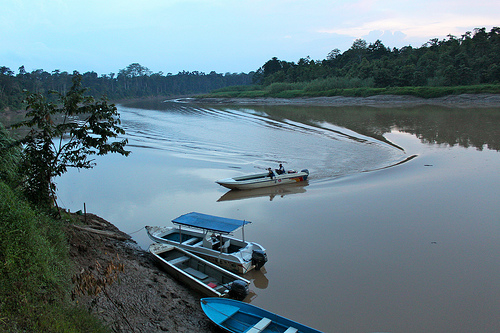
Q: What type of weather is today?
A: It is clear.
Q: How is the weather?
A: It is clear.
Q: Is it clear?
A: Yes, it is clear.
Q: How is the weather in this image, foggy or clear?
A: It is clear.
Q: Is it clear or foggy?
A: It is clear.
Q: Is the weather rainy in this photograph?
A: No, it is clear.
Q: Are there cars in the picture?
A: No, there are no cars.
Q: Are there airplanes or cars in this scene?
A: No, there are no cars or airplanes.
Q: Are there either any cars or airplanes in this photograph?
A: No, there are no cars or airplanes.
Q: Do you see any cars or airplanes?
A: No, there are no cars or airplanes.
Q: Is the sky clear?
A: Yes, the sky is clear.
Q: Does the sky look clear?
A: Yes, the sky is clear.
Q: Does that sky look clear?
A: Yes, the sky is clear.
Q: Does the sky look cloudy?
A: No, the sky is clear.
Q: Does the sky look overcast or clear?
A: The sky is clear.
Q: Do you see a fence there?
A: No, there are no fences.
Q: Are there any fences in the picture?
A: No, there are no fences.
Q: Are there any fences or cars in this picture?
A: No, there are no fences or cars.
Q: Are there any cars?
A: No, there are no cars.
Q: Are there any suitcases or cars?
A: No, there are no cars or suitcases.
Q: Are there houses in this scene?
A: No, there are no houses.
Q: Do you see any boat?
A: Yes, there is a boat.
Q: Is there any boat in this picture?
A: Yes, there is a boat.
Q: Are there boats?
A: Yes, there is a boat.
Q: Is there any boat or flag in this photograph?
A: Yes, there is a boat.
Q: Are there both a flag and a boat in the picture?
A: No, there is a boat but no flags.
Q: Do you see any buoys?
A: No, there are no buoys.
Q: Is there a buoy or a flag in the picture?
A: No, there are no buoys or flags.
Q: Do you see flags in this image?
A: No, there are no flags.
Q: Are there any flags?
A: No, there are no flags.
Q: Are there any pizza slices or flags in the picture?
A: No, there are no flags or pizza slices.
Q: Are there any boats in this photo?
A: Yes, there is a boat.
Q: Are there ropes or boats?
A: Yes, there is a boat.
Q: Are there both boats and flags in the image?
A: No, there is a boat but no flags.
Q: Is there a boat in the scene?
A: Yes, there is a boat.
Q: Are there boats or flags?
A: Yes, there is a boat.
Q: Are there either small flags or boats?
A: Yes, there is a small boat.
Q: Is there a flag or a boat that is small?
A: Yes, the boat is small.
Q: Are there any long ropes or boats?
A: Yes, there is a long boat.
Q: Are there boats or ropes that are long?
A: Yes, the boat is long.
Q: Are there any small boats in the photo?
A: Yes, there is a small boat.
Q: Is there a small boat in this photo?
A: Yes, there is a small boat.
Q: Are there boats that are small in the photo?
A: Yes, there is a small boat.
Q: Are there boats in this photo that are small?
A: Yes, there is a boat that is small.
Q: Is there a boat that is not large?
A: Yes, there is a small boat.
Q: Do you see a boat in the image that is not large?
A: Yes, there is a small boat.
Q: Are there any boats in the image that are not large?
A: Yes, there is a small boat.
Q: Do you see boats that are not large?
A: Yes, there is a small boat.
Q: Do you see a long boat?
A: Yes, there is a long boat.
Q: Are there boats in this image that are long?
A: Yes, there is a boat that is long.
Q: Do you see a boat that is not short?
A: Yes, there is a long boat.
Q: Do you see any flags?
A: No, there are no flags.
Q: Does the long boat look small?
A: Yes, the boat is small.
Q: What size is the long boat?
A: The boat is small.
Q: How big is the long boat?
A: The boat is small.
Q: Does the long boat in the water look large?
A: No, the boat is small.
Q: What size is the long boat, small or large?
A: The boat is small.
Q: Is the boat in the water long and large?
A: No, the boat is long but small.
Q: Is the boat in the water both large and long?
A: No, the boat is long but small.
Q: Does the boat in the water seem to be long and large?
A: No, the boat is long but small.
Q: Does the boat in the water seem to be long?
A: Yes, the boat is long.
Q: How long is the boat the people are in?
A: The boat is long.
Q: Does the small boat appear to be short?
A: No, the boat is long.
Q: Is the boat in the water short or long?
A: The boat is long.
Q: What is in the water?
A: The boat is in the water.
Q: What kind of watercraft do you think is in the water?
A: The watercraft is a boat.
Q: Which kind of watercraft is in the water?
A: The watercraft is a boat.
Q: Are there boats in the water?
A: Yes, there is a boat in the water.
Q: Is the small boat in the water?
A: Yes, the boat is in the water.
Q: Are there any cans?
A: No, there are no cans.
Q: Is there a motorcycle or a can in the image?
A: No, there are no cans or motorcycles.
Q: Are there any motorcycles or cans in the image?
A: No, there are no cans or motorcycles.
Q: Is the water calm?
A: Yes, the water is calm.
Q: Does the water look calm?
A: Yes, the water is calm.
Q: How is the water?
A: The water is calm.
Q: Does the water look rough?
A: No, the water is calm.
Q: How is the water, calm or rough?
A: The water is calm.